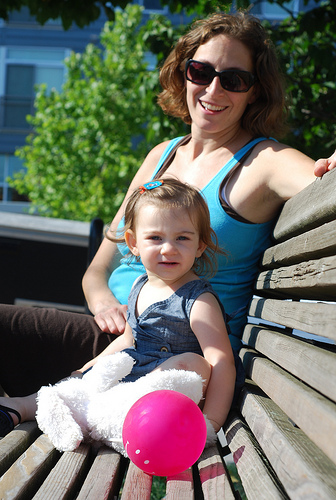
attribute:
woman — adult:
[1, 10, 320, 369]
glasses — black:
[184, 56, 256, 95]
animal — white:
[36, 352, 208, 451]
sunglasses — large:
[183, 55, 259, 97]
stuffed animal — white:
[36, 349, 217, 451]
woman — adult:
[0, 6, 335, 396]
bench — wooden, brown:
[3, 163, 333, 498]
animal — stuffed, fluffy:
[36, 350, 216, 458]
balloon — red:
[120, 386, 211, 478]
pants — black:
[0, 303, 121, 396]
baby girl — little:
[0, 176, 237, 431]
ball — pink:
[107, 380, 198, 484]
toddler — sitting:
[125, 179, 239, 445]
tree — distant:
[17, 8, 179, 234]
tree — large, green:
[66, 34, 128, 156]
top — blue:
[123, 122, 263, 342]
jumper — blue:
[120, 277, 229, 382]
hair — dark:
[156, 13, 290, 142]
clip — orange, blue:
[136, 175, 168, 197]